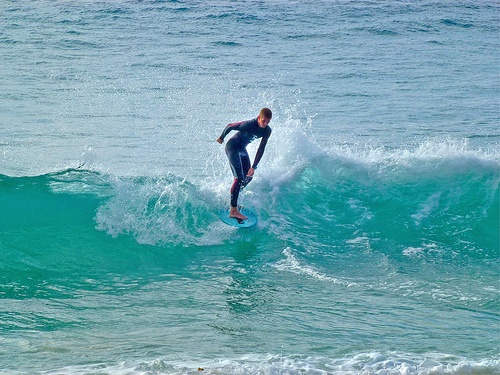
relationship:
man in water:
[214, 107, 275, 222] [78, 209, 365, 290]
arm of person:
[217, 119, 242, 143] [217, 106, 272, 223]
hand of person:
[205, 135, 230, 152] [193, 96, 313, 240]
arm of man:
[220, 122, 245, 140] [214, 107, 275, 222]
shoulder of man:
[238, 119, 250, 131] [214, 107, 275, 222]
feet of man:
[228, 204, 249, 222] [214, 107, 275, 222]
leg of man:
[225, 148, 247, 220] [214, 107, 275, 222]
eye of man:
[262, 116, 266, 123] [214, 107, 275, 222]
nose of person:
[260, 121, 270, 128] [205, 90, 270, 226]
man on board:
[214, 107, 275, 222] [211, 197, 257, 231]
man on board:
[214, 107, 275, 222] [218, 202, 258, 227]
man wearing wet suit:
[214, 107, 275, 222] [220, 116, 275, 188]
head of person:
[255, 107, 270, 129] [215, 105, 274, 230]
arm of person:
[240, 135, 267, 181] [220, 95, 276, 245]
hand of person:
[244, 165, 257, 175] [220, 101, 278, 237]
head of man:
[255, 107, 270, 129] [193, 88, 288, 240]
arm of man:
[220, 122, 245, 140] [197, 98, 295, 242]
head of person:
[248, 99, 282, 141] [220, 90, 284, 247]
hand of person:
[242, 165, 258, 181] [214, 105, 276, 221]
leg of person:
[225, 148, 247, 208] [207, 88, 286, 231]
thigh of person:
[225, 150, 247, 185] [211, 79, 278, 248]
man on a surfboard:
[214, 107, 275, 222] [222, 213, 255, 227]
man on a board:
[214, 107, 275, 222] [214, 194, 261, 232]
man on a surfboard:
[214, 107, 275, 222] [206, 187, 316, 238]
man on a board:
[214, 107, 275, 222] [210, 201, 259, 229]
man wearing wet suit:
[187, 113, 302, 248] [201, 121, 271, 201]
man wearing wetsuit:
[214, 107, 275, 222] [226, 118, 270, 214]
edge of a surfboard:
[217, 213, 228, 225] [217, 200, 264, 242]